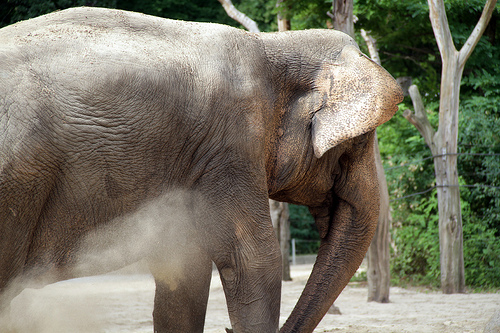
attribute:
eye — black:
[356, 130, 375, 165]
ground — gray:
[452, 156, 463, 183]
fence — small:
[282, 238, 321, 264]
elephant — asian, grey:
[0, 5, 407, 332]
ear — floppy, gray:
[305, 40, 405, 157]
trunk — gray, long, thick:
[298, 147, 401, 319]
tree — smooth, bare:
[397, 4, 492, 299]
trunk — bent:
[221, 162, 384, 331]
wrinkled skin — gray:
[1, 29, 374, 331]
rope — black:
[414, 154, 474, 196]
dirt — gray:
[366, 303, 426, 317]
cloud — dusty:
[110, 224, 166, 264]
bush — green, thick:
[426, 177, 475, 286]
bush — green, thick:
[409, 107, 498, 212]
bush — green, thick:
[460, 101, 498, 229]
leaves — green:
[159, 0, 499, 293]